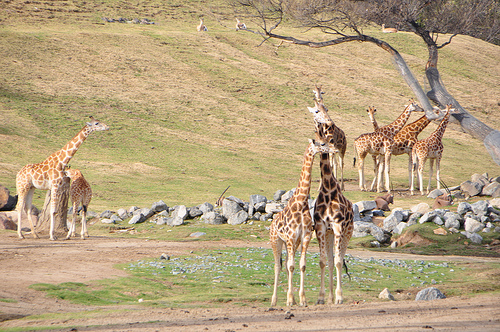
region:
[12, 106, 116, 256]
Two giraffes standing up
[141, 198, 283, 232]
A pile of rocks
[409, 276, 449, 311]
A single rock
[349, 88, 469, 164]
Four giraffes by a tree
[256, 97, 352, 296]
Three giraffes standing in grass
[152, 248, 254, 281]
A bunch of small rocks in the grass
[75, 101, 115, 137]
The head of a giraffe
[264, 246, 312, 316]
The legs of a giraffe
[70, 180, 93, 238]
A giraffe from the rear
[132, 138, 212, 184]
Grass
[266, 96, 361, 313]
Two tallest giraffes forefront.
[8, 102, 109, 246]
One standing one stooping.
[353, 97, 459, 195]
Four giraffes near tree branch.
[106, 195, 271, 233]
Natural rock wall formed.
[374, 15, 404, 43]
Single bovine animal distance.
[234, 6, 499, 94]
Double long bare branch.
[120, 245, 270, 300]
Trampled sparse grass sand.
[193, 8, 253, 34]
Possibly two additional animals.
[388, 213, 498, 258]
Green moss adheres rocks.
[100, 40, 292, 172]
Sloping hill toward giraffes.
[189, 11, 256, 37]
animals on top of hill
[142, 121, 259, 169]
green grass on hill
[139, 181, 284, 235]
rocks in a line on the ground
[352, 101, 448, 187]
four giraffe under tree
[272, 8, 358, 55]
tree branch with no leaves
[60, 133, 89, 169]
long neck on giraffe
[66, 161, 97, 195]
giraffe bending its neck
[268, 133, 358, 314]
two giraffe close together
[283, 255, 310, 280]
knobby knees on giraffe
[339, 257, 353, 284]
tail on back of giraffe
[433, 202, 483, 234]
part of a pile of stones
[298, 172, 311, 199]
neck of a a giraffe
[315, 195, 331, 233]
chest of a giraffe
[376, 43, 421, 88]
part of a branch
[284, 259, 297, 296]
right leg of a giraffe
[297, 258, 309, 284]
left leg of the giraffe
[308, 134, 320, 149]
right ear of a giraffe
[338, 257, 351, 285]
tail of a giraffe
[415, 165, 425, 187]
left hind leg of a giraffe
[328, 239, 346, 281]
left front leg of a giraffe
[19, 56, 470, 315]
giraffes photographed in the wild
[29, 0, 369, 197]
large green and brown hill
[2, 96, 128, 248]
adult giraffe with a baby giraffe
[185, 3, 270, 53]
two animals laying on hill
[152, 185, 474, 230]
row of large rocks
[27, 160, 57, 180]
brown spots on giraffe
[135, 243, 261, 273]
small stones scattered on grass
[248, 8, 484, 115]
large tree with no leaves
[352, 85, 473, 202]
group of giraffes near tree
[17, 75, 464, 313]
nine giraffes in the wild